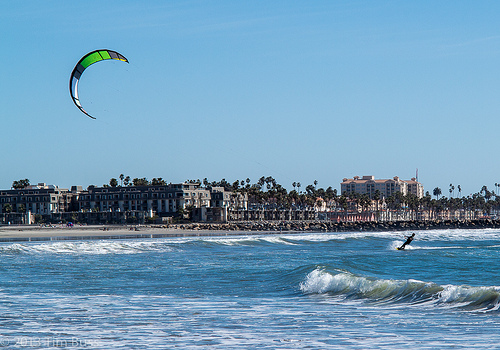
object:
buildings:
[0, 183, 249, 223]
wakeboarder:
[397, 232, 416, 251]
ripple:
[164, 311, 267, 344]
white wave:
[300, 268, 499, 310]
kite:
[68, 48, 131, 119]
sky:
[410, 0, 498, 61]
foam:
[19, 241, 152, 259]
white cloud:
[191, 15, 248, 33]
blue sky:
[26, 6, 156, 42]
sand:
[0, 224, 172, 238]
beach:
[0, 218, 499, 241]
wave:
[250, 223, 335, 253]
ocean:
[0, 220, 499, 348]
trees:
[251, 174, 288, 204]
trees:
[463, 185, 499, 207]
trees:
[300, 179, 321, 205]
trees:
[323, 182, 340, 204]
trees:
[404, 192, 421, 209]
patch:
[84, 220, 99, 227]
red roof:
[367, 178, 389, 182]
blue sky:
[292, 53, 402, 134]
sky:
[5, 129, 142, 176]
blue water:
[21, 260, 290, 289]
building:
[338, 174, 425, 208]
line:
[0, 225, 499, 241]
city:
[0, 164, 499, 228]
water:
[0, 225, 499, 349]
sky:
[167, 122, 236, 168]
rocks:
[291, 219, 360, 231]